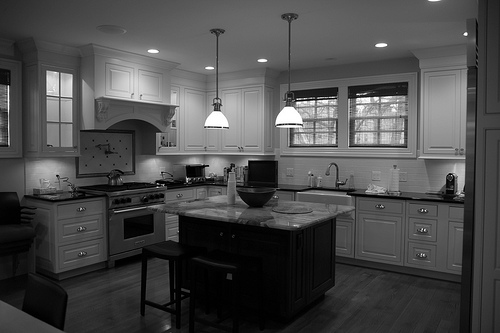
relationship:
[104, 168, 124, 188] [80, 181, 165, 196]
kettle on stove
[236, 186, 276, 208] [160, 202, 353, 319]
bowl on kitcen island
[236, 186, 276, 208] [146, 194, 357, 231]
bowl on bar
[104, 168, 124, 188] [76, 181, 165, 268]
kettle on stove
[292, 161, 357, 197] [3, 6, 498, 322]
sink in kitchen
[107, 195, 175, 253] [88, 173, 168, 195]
oven with stovetop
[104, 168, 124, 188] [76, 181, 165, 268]
kettle sitting on stove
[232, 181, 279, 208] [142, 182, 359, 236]
bowl sitting on counter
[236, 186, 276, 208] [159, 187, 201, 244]
bowl on cabinet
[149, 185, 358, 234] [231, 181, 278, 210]
island has bowl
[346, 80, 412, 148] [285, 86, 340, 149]
windows next to window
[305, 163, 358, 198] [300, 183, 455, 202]
sink on counters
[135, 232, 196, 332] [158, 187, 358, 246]
chair under bar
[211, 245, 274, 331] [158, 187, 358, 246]
chair under bar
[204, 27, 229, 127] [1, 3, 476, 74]
light hanging from ceiling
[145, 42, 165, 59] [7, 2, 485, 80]
light in ceiling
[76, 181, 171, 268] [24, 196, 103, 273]
stove next to cabinet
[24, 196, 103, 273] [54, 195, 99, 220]
cabinet has drawer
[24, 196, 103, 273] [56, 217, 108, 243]
cabinet has drawer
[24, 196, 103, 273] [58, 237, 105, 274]
cabinet has drawer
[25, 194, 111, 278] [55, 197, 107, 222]
cabinet has drawer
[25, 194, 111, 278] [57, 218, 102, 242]
cabinet has drawer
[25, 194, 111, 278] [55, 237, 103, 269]
cabinet has drawer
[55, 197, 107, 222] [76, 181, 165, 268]
drawer next to stove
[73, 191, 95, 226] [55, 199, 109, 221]
knob on drawer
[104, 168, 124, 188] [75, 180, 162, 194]
kettle on stove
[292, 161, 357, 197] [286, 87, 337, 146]
sink under window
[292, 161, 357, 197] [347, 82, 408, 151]
sink under window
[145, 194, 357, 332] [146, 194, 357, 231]
island topped with bar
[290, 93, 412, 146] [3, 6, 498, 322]
window in a kitchen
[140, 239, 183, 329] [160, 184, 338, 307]
chair at an island